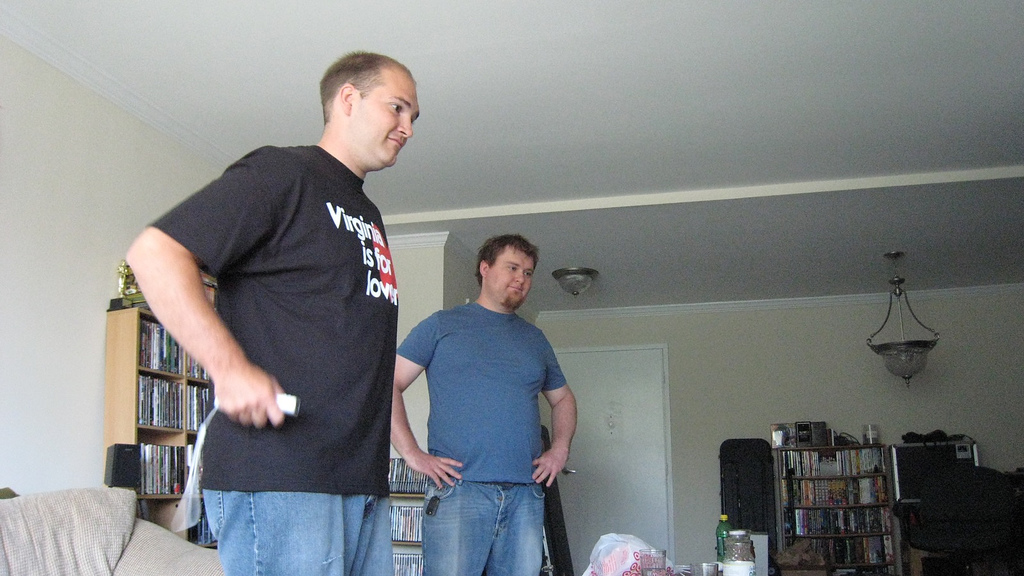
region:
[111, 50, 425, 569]
man in a black shirt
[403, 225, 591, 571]
man in a blue shirt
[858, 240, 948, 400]
silver and glass chandelier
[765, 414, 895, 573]
a bookcase full of videos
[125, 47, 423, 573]
man holding a Wii controller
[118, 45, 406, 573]
a man wearing blue jeans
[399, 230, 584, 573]
a man in blue jeans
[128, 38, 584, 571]
two men standing up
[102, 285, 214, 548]
brown bookcase of books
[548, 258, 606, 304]
a silver and glass ceiling light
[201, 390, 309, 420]
white wii remote in hand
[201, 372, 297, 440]
right hand on the man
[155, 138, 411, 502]
black shirt on the man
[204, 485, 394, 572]
blue jeans on the man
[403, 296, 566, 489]
blue shirt on man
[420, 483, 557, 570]
blue jeans on the man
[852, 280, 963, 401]
light hanging from ceiling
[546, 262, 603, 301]
light fixture on ceiling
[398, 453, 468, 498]
right hand on man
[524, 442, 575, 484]
left hand on man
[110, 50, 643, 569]
Two men playing videogames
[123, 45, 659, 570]
Two people playing videogames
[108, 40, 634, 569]
Two men holding controllers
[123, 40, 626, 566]
Two people holding controllers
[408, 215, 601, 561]
Man wearing a blue shirt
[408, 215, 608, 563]
Person in a blue shirt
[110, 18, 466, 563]
Man in a black shirt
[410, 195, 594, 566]
Man in blue jeans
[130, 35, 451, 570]
Man wearing blue jeans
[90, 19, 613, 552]
two men standing next to each other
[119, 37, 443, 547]
a man playing nintendo wii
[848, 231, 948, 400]
a light fixture hanging from the ceiling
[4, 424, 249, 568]
the edge of a chair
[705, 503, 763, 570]
two drink bottles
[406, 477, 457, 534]
a car door opener hanging from a man's pocket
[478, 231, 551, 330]
man with facial hair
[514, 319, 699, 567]
a white door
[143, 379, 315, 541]
a nintendo wii remote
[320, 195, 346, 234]
white letter on shirt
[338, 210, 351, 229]
white letter on shirt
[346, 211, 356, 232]
white letter on shirt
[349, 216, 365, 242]
white letter on shirt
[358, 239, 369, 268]
white letter on shirt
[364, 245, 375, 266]
white letter on shirt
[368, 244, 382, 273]
white letter on shirt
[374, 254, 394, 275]
white letter on shirt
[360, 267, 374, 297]
white letter on shirt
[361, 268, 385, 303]
white letter on shirt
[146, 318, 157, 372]
DVD case in the wooden book shelf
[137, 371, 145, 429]
DVD case in the wooden book shelf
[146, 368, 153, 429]
DVD case in the wooden book shelf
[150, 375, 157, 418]
DVD case in the wooden book shelf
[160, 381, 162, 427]
DVD case in the wooden book shelf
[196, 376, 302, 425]
Wii controller in man's hand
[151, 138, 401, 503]
black shirt on the man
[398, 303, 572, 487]
blue shirt on the man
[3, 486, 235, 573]
tan couch behind the man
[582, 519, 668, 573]
white plastic bag in the room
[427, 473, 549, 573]
blue jeans on man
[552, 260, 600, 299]
light attached to the ceiling